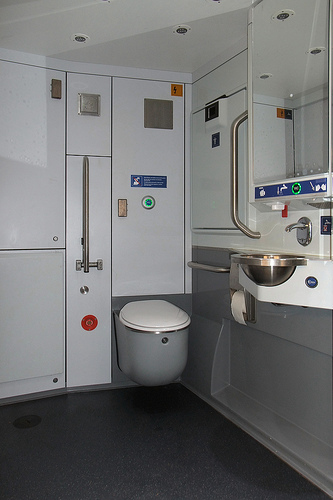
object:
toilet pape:
[231, 290, 247, 327]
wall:
[110, 73, 184, 298]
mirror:
[251, 0, 329, 187]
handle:
[82, 158, 89, 271]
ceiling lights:
[72, 34, 88, 42]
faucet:
[285, 223, 307, 234]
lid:
[121, 300, 190, 329]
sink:
[230, 251, 307, 288]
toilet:
[113, 297, 190, 385]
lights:
[172, 26, 192, 36]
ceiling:
[0, 0, 246, 72]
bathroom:
[0, 0, 333, 499]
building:
[0, 42, 191, 405]